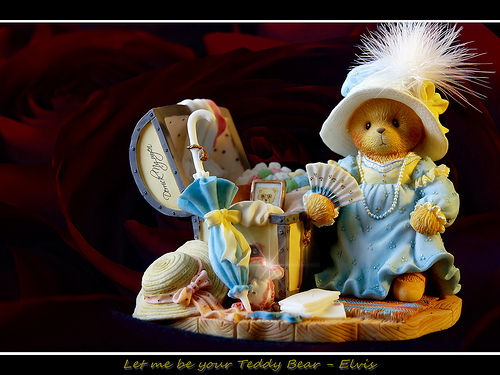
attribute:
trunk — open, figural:
[127, 105, 318, 297]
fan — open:
[303, 158, 365, 208]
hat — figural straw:
[318, 23, 464, 160]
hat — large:
[317, 23, 497, 161]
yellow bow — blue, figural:
[416, 77, 449, 135]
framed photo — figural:
[249, 177, 287, 212]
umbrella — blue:
[178, 104, 256, 304]